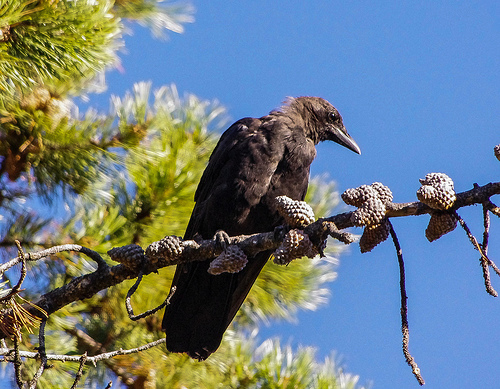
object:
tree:
[1, 1, 496, 387]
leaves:
[3, 1, 33, 17]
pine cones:
[415, 169, 457, 214]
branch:
[4, 181, 498, 343]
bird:
[161, 95, 362, 361]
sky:
[1, 0, 499, 388]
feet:
[210, 230, 234, 248]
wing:
[160, 117, 308, 360]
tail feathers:
[160, 236, 276, 362]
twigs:
[438, 206, 500, 276]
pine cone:
[106, 242, 147, 270]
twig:
[386, 217, 426, 385]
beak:
[328, 126, 363, 154]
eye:
[329, 111, 340, 121]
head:
[286, 94, 363, 156]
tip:
[350, 141, 361, 155]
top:
[299, 94, 341, 123]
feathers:
[192, 116, 254, 199]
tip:
[476, 278, 500, 298]